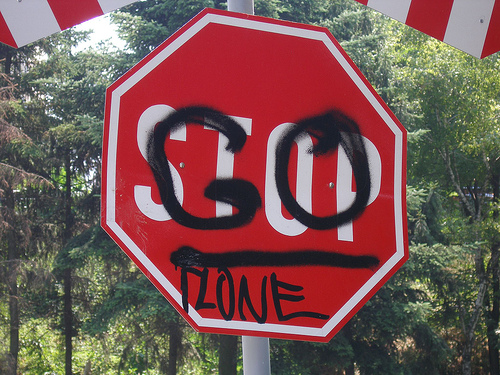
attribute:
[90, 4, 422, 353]
sign — red, white, octagon, flat, metal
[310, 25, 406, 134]
trim — white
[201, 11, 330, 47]
trim — red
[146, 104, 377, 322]
writing — print, legible, white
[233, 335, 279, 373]
pole — metal, long, silver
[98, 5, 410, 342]
stop sign — painted over, flat, red, octagon, metal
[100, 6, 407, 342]
sign — thin, octagon, red, white, metal, flat, painted, graffiti